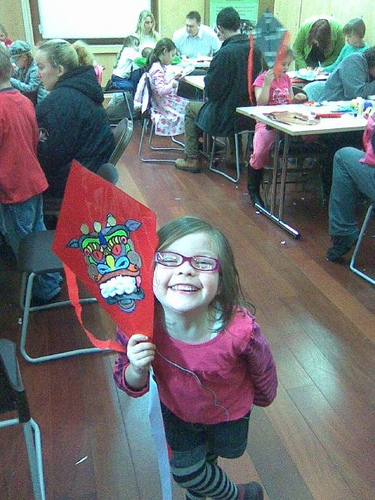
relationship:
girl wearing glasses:
[106, 213, 275, 498] [157, 253, 220, 273]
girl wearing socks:
[106, 213, 275, 498] [168, 462, 259, 498]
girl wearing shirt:
[106, 213, 275, 498] [122, 295, 277, 411]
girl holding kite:
[106, 213, 275, 498] [52, 159, 160, 353]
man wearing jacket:
[203, 40, 269, 139] [202, 34, 264, 138]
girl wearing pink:
[251, 39, 293, 193] [253, 73, 298, 103]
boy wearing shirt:
[0, 41, 50, 269] [0, 88, 49, 211]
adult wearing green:
[289, 13, 340, 76] [292, 43, 341, 68]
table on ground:
[233, 89, 373, 245] [5, 112, 374, 495]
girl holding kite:
[251, 39, 293, 193] [247, 7, 286, 72]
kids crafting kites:
[131, 22, 365, 224] [254, 13, 290, 72]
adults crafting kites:
[2, 21, 374, 255] [254, 13, 290, 72]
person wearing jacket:
[289, 13, 340, 76] [295, 24, 342, 72]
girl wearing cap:
[6, 34, 38, 105] [9, 38, 31, 61]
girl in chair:
[147, 39, 199, 145] [139, 75, 186, 166]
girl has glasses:
[106, 213, 275, 498] [157, 253, 220, 273]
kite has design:
[52, 159, 160, 353] [64, 213, 151, 311]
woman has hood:
[29, 32, 114, 199] [60, 62, 103, 107]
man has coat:
[203, 40, 269, 139] [202, 34, 264, 138]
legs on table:
[269, 135, 288, 221] [233, 89, 373, 245]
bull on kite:
[64, 213, 151, 311] [52, 159, 160, 353]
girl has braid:
[251, 39, 293, 193] [115, 41, 121, 77]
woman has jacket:
[29, 32, 114, 199] [32, 76, 110, 199]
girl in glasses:
[106, 213, 275, 498] [157, 253, 220, 273]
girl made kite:
[106, 213, 275, 498] [52, 159, 160, 353]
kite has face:
[52, 159, 160, 353] [64, 213, 151, 311]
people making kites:
[2, 21, 374, 255] [254, 13, 290, 72]